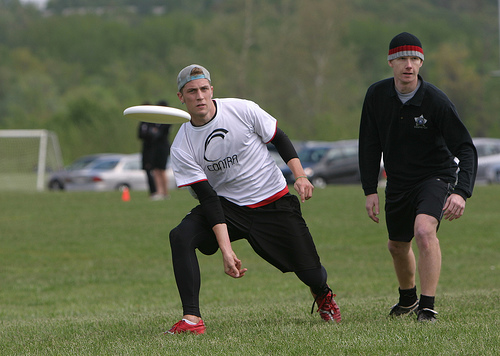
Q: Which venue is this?
A: This is a park.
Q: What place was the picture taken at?
A: It was taken at the park.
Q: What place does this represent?
A: It represents the park.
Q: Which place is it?
A: It is a park.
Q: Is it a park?
A: Yes, it is a park.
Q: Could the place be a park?
A: Yes, it is a park.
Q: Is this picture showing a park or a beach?
A: It is showing a park.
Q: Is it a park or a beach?
A: It is a park.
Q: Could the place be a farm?
A: No, it is a park.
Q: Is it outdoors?
A: Yes, it is outdoors.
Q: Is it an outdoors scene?
A: Yes, it is outdoors.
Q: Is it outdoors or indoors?
A: It is outdoors.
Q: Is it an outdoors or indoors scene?
A: It is outdoors.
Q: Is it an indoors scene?
A: No, it is outdoors.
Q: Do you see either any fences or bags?
A: No, there are no fences or bags.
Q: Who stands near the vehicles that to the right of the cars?
A: The people stand near the vehicles.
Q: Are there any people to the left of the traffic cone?
A: No, the people are to the right of the traffic cone.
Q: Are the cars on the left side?
A: Yes, the cars are on the left of the image.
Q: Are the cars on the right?
A: No, the cars are on the left of the image.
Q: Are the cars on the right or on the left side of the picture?
A: The cars are on the left of the image.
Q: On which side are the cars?
A: The cars are on the left of the image.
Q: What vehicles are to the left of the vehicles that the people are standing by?
A: The vehicles are cars.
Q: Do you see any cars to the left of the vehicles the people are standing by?
A: Yes, there are cars to the left of the vehicles.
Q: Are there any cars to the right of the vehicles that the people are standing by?
A: No, the cars are to the left of the vehicles.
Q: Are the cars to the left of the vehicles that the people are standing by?
A: Yes, the cars are to the left of the vehicles.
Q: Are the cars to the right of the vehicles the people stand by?
A: No, the cars are to the left of the vehicles.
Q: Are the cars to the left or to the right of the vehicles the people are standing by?
A: The cars are to the left of the vehicles.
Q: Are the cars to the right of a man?
A: No, the cars are to the left of a man.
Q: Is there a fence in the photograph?
A: No, there are no fences.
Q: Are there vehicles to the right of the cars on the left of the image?
A: Yes, there are vehicles to the right of the cars.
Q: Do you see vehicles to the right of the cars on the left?
A: Yes, there are vehicles to the right of the cars.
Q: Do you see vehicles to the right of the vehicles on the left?
A: Yes, there are vehicles to the right of the cars.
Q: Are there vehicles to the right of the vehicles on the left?
A: Yes, there are vehicles to the right of the cars.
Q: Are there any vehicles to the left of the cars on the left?
A: No, the vehicles are to the right of the cars.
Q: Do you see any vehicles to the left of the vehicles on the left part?
A: No, the vehicles are to the right of the cars.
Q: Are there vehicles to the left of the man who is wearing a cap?
A: Yes, there are vehicles to the left of the man.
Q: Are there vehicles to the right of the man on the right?
A: No, the vehicles are to the left of the man.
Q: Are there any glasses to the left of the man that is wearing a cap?
A: No, there are vehicles to the left of the man.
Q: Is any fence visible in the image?
A: No, there are no fences.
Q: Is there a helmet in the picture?
A: No, there are no helmets.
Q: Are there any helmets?
A: No, there are no helmets.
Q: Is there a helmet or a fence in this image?
A: No, there are no helmets or fences.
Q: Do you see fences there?
A: No, there are no fences.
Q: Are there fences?
A: No, there are no fences.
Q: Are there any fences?
A: No, there are no fences.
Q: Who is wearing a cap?
A: The man is wearing a cap.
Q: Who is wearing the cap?
A: The man is wearing a cap.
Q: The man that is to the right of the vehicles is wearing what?
A: The man is wearing a cap.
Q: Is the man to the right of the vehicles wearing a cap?
A: Yes, the man is wearing a cap.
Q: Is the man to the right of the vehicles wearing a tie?
A: No, the man is wearing a cap.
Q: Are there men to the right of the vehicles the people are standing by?
A: Yes, there is a man to the right of the vehicles.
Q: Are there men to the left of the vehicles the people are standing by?
A: No, the man is to the right of the vehicles.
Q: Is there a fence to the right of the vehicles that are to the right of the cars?
A: No, there is a man to the right of the vehicles.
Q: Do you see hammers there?
A: No, there are no hammers.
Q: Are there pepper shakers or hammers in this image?
A: No, there are no hammers or pepper shakers.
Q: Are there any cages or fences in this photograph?
A: No, there are no fences or cages.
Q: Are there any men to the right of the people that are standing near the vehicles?
A: Yes, there is a man to the right of the people.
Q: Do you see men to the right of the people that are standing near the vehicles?
A: Yes, there is a man to the right of the people.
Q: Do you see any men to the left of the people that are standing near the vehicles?
A: No, the man is to the right of the people.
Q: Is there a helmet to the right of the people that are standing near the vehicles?
A: No, there is a man to the right of the people.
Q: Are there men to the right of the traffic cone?
A: Yes, there is a man to the right of the traffic cone.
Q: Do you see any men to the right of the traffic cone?
A: Yes, there is a man to the right of the traffic cone.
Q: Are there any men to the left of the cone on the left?
A: No, the man is to the right of the cone.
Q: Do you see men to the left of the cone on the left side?
A: No, the man is to the right of the cone.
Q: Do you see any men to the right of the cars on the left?
A: Yes, there is a man to the right of the cars.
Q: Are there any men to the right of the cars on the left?
A: Yes, there is a man to the right of the cars.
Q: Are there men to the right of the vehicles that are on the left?
A: Yes, there is a man to the right of the cars.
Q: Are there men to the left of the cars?
A: No, the man is to the right of the cars.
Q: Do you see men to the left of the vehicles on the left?
A: No, the man is to the right of the cars.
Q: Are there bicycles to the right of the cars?
A: No, there is a man to the right of the cars.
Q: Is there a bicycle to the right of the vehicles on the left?
A: No, there is a man to the right of the cars.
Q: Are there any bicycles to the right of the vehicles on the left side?
A: No, there is a man to the right of the cars.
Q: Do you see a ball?
A: No, there are no balls.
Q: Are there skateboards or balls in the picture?
A: No, there are no balls or skateboards.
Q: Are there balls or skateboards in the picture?
A: No, there are no balls or skateboards.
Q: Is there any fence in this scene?
A: No, there are no fences.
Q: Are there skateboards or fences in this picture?
A: No, there are no fences or skateboards.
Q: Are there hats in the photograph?
A: Yes, there is a hat.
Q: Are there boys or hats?
A: Yes, there is a hat.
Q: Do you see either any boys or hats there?
A: Yes, there is a hat.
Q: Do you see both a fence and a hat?
A: No, there is a hat but no fences.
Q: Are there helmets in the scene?
A: No, there are no helmets.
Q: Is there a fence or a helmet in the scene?
A: No, there are no helmets or fences.